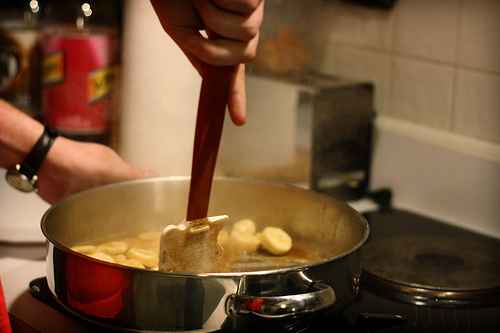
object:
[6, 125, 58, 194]
watch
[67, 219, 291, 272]
banana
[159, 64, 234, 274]
spatula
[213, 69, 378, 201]
toaster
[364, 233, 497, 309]
burner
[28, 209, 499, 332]
stove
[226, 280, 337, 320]
handle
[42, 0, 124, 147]
bottle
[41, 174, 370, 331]
pan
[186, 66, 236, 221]
handle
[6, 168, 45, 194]
face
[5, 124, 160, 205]
hand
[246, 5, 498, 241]
wall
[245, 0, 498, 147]
tile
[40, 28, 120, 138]
can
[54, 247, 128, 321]
reflection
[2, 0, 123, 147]
bottles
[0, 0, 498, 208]
background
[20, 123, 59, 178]
band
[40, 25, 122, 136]
label